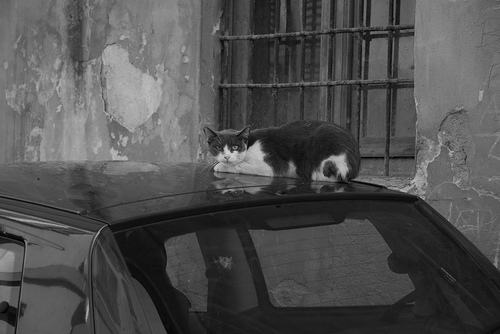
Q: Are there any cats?
A: Yes, there is a cat.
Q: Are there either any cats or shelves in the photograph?
A: Yes, there is a cat.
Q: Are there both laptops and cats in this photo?
A: No, there is a cat but no laptops.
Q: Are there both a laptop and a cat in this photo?
A: No, there is a cat but no laptops.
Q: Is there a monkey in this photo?
A: No, there are no monkeys.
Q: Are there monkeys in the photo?
A: No, there are no monkeys.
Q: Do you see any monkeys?
A: No, there are no monkeys.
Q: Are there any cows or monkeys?
A: No, there are no monkeys or cows.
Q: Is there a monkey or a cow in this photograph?
A: No, there are no monkeys or cows.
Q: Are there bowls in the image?
A: No, there are no bowls.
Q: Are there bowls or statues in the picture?
A: No, there are no bowls or statues.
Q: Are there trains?
A: No, there are no trains.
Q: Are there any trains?
A: No, there are no trains.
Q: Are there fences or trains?
A: No, there are no trains or fences.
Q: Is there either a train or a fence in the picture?
A: No, there are no trains or fences.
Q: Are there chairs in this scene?
A: No, there are no chairs.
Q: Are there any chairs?
A: No, there are no chairs.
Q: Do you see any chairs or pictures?
A: No, there are no chairs or pictures.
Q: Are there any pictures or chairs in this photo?
A: No, there are no chairs or pictures.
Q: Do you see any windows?
A: Yes, there is a window.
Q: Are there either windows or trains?
A: Yes, there is a window.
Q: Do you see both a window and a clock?
A: No, there is a window but no clocks.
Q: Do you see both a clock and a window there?
A: No, there is a window but no clocks.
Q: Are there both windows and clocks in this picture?
A: No, there is a window but no clocks.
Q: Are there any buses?
A: No, there are no buses.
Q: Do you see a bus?
A: No, there are no buses.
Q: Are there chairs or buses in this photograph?
A: No, there are no buses or chairs.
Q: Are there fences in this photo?
A: No, there are no fences.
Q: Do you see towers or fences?
A: No, there are no fences or towers.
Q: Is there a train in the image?
A: No, there are no trains.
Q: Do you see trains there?
A: No, there are no trains.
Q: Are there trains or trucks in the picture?
A: No, there are no trains or trucks.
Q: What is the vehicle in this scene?
A: The vehicle is a car.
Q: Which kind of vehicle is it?
A: The vehicle is a car.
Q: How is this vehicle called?
A: That is a car.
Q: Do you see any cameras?
A: Yes, there is a camera.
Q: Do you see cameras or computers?
A: Yes, there is a camera.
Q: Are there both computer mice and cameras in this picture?
A: No, there is a camera but no computer mice.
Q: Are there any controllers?
A: No, there are no controllers.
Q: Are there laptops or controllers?
A: No, there are no controllers or laptops.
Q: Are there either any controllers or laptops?
A: No, there are no controllers or laptops.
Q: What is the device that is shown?
A: The device is a camera.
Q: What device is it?
A: The device is a camera.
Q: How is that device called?
A: This is a camera.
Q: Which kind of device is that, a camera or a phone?
A: This is a camera.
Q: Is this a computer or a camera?
A: This is a camera.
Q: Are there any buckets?
A: No, there are no buckets.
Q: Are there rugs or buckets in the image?
A: No, there are no buckets or rugs.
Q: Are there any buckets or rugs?
A: No, there are no buckets or rugs.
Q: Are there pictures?
A: No, there are no pictures.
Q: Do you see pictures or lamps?
A: No, there are no pictures or lamps.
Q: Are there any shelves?
A: No, there are no shelves.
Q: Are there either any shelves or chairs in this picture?
A: No, there are no shelves or chairs.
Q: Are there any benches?
A: No, there are no benches.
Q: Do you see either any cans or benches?
A: No, there are no benches or cans.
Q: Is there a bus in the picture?
A: No, there are no buses.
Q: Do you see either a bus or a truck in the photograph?
A: No, there are no buses or trucks.